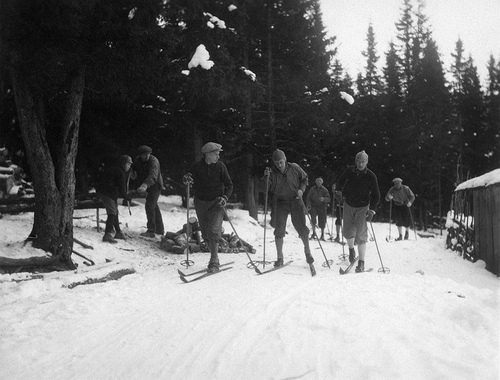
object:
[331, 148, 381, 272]
person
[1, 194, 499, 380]
snow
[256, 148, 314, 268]
person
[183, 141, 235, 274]
person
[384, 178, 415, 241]
person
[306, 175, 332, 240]
person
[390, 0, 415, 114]
tree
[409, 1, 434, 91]
tree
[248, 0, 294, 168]
tree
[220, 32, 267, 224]
tree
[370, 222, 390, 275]
ski pole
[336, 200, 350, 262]
ski pole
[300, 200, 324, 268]
ski pole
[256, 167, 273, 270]
ski pole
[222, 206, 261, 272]
ski pole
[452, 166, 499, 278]
cabin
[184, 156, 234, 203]
sweater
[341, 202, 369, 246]
shorts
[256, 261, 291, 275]
ski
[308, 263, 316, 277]
ski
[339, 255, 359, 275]
ski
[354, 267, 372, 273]
ski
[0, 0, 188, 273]
tree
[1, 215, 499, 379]
path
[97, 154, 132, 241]
person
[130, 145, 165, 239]
person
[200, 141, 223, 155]
hat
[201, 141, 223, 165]
person's head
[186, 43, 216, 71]
snow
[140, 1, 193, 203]
tree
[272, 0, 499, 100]
sky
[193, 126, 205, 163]
tree trunk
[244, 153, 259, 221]
tree trunk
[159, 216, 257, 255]
pile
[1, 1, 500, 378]
scene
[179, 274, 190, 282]
tip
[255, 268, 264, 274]
tip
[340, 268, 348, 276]
tip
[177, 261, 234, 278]
ski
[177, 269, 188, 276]
tip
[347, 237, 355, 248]
sock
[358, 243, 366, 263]
sock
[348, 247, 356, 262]
ski boot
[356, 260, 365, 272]
ski boot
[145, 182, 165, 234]
pants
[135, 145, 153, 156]
cap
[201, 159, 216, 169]
shirt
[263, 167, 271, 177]
hand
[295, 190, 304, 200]
hand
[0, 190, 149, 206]
wood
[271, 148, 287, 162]
hat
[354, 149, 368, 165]
hat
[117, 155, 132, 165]
hat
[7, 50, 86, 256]
tree trunk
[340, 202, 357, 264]
left leg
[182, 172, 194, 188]
left hand